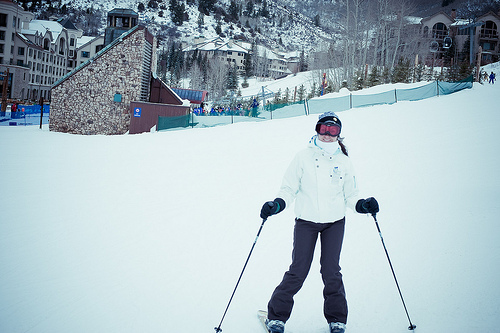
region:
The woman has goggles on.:
[306, 113, 351, 143]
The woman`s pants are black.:
[260, 210, 360, 321]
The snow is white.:
[342, 86, 452, 203]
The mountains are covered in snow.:
[145, 4, 317, 67]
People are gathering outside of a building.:
[180, 85, 276, 115]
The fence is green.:
[258, 75, 435, 132]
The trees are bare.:
[320, 0, 413, 87]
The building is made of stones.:
[50, 21, 177, 136]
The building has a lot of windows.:
[404, 2, 498, 87]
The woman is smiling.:
[296, 105, 354, 184]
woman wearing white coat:
[261, 107, 384, 331]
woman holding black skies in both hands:
[258, 105, 382, 331]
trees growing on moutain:
[0, 4, 334, 69]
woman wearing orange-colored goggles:
[261, 109, 389, 331]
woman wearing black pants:
[258, 105, 386, 332]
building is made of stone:
[48, 22, 159, 133]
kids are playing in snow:
[480, 70, 497, 85]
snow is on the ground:
[0, 0, 495, 331]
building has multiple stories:
[0, 2, 80, 106]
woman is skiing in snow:
[254, 108, 383, 331]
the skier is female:
[190, 68, 437, 310]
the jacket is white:
[211, 52, 463, 312]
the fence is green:
[217, 85, 433, 185]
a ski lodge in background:
[23, 15, 255, 210]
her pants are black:
[207, 59, 477, 267]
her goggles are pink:
[250, 79, 483, 224]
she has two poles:
[233, 155, 498, 270]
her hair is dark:
[223, 67, 471, 289]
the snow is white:
[83, 164, 218, 212]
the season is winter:
[106, 15, 481, 285]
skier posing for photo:
[223, 102, 425, 323]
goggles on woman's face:
[304, 115, 344, 140]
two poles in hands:
[225, 200, 410, 295]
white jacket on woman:
[274, 140, 366, 226]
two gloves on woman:
[255, 195, 385, 227]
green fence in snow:
[349, 78, 429, 112]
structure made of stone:
[67, 54, 132, 124]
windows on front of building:
[25, 38, 70, 88]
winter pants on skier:
[269, 212, 356, 322]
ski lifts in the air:
[417, 28, 457, 58]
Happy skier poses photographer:
[236, 100, 400, 330]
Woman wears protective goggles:
[297, 108, 345, 202]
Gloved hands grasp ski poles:
[215, 188, 411, 331]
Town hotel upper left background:
[2, 10, 68, 127]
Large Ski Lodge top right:
[393, 15, 499, 76]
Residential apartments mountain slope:
[178, 34, 292, 84]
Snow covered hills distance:
[64, 5, 412, 54]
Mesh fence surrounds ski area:
[148, 70, 480, 127]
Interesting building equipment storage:
[45, 24, 200, 149]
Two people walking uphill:
[468, 58, 499, 85]